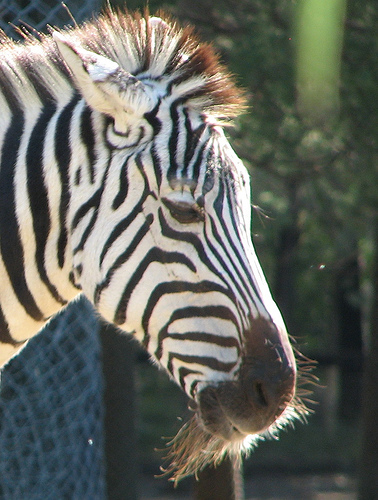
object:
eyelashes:
[251, 203, 277, 230]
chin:
[198, 390, 247, 440]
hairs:
[270, 334, 327, 440]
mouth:
[209, 387, 249, 442]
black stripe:
[153, 246, 197, 273]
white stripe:
[153, 264, 175, 276]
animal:
[0, 0, 325, 489]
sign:
[203, 274, 248, 326]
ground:
[350, 86, 361, 102]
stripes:
[140, 291, 158, 337]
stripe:
[205, 212, 255, 327]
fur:
[3, 138, 73, 260]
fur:
[153, 12, 197, 82]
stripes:
[173, 272, 204, 299]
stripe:
[162, 329, 241, 356]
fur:
[135, 309, 165, 345]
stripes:
[67, 262, 104, 297]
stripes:
[0, 117, 52, 180]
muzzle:
[198, 313, 297, 443]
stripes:
[135, 72, 173, 111]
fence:
[0, 300, 106, 500]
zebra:
[0, 1, 327, 489]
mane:
[0, 0, 255, 128]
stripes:
[183, 336, 238, 383]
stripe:
[74, 167, 80, 184]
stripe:
[166, 97, 181, 190]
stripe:
[113, 247, 197, 325]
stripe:
[167, 352, 237, 373]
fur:
[0, 27, 48, 101]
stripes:
[146, 214, 198, 249]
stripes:
[50, 107, 87, 153]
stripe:
[69, 270, 83, 290]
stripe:
[25, 106, 67, 307]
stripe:
[0, 302, 28, 349]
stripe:
[80, 102, 100, 185]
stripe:
[74, 165, 82, 185]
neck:
[0, 86, 84, 375]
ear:
[52, 31, 151, 133]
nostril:
[254, 382, 268, 407]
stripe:
[142, 280, 249, 348]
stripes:
[217, 213, 249, 253]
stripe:
[54, 92, 79, 269]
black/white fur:
[0, 0, 245, 125]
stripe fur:
[97, 168, 137, 247]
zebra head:
[48, 0, 329, 489]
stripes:
[235, 285, 256, 314]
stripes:
[221, 254, 256, 292]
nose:
[244, 366, 297, 428]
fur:
[112, 0, 190, 71]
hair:
[153, 403, 264, 488]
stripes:
[220, 281, 247, 341]